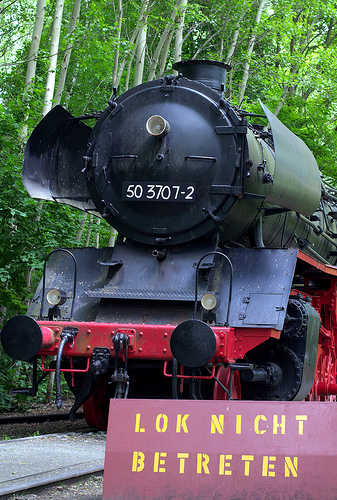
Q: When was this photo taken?
A: On a trip to Europe.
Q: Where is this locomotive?
A: In Germany.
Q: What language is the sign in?
A: German.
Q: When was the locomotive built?
A: A hundred years ago.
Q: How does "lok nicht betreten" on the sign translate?
A: Do Not Enter.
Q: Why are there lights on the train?
A: To operate the train at night.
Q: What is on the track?
A: A train.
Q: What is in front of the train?
A: A sign.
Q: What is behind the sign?
A: A train.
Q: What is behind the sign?
A: A train.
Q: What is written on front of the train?
A: Numbers.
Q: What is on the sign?
A: Yellow letters.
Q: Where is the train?
A: On a track around some trees.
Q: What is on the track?
A: A black train.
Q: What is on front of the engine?
A: A lamp.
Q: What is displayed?
A: Train.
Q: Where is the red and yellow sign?
A: On the tracks.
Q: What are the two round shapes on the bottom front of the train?
A: Cattle guard.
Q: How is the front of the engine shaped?
A: Round.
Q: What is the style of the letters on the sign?
A: Block.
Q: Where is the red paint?
A: Bottom half of the train.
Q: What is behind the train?
A: Trees.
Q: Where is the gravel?
A: On the sides of the tracks.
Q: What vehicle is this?
A: A train.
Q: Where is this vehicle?
A: In Europe.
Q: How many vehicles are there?
A: One.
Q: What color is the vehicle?
A: Black.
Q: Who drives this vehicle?
A: An engineer.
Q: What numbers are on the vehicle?
A: 50 3707-2.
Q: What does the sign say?
A: Lok nicht betreten.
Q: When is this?
A: Summer.